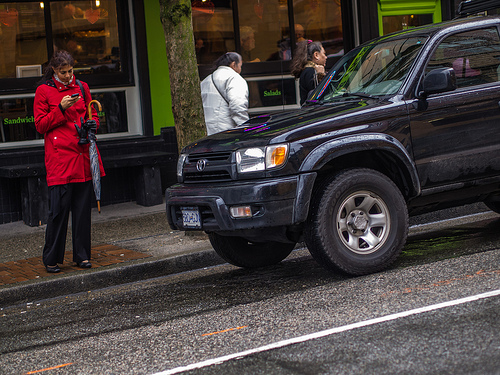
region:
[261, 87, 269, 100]
green letter on sign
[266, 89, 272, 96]
green letter on sign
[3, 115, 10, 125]
green letter on sign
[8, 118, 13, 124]
green letter on sign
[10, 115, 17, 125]
green letter on sign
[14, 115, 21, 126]
green letter on sign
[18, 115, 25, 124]
green letter on sign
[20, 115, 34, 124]
green letter on sign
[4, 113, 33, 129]
green letters on sign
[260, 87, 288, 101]
green letters on sign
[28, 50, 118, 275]
A woman in red jacket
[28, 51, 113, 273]
A woman holding an umbrella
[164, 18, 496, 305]
Black Toyota SUV on the right lane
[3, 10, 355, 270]
People standing on the side walk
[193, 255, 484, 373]
White line on the black asphalt road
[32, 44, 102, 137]
A woman reading messages on the cellphone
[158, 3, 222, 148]
Trunk of the tree planted on the side walk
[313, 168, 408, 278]
Black tire with silver rim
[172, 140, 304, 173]
Headlights of the car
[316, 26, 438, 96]
Front windshield and vipers of the car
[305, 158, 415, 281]
the left front wheel of a car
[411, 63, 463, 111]
the left mirror of a car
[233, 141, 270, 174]
the left headlight of a car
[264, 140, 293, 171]
the left turn signal of a car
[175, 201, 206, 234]
the front license plate of a car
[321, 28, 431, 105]
the front windshield of a car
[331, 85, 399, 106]
a windshield wiper on a window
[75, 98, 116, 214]
a woman holding an umbrella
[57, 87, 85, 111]
a cell phone in someone's hand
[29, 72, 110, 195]
a woman in a red coat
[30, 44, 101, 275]
woman standing on edge of sidewalk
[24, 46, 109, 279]
woman dressed in red coat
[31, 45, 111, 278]
woman carrying a folded umbrella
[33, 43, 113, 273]
woman looking at her cell phone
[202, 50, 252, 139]
woman walking down sidewalk with head slightly lowered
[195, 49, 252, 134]
woman walking down sidewalk with a white coat on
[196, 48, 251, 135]
woman walking down sidewalk with purse draped across chest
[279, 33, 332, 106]
woman with pony tail walking down sidewalk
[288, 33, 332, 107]
woman in black shirt walking down sidewalk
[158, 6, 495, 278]
black suv type vehicle parked at curb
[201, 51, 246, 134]
a woman wearing a white coat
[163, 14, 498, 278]
a black parked car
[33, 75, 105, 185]
woman wearing a red coat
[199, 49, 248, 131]
a woman walking on a sidewalk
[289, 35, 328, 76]
a woman with long brown hair in a pony tail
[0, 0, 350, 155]
store front of a restaurant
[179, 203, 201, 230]
a blue and white license plate on a car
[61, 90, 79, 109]
a woman holding a cell phone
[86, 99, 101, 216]
a woman holding an umbrella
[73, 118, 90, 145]
a black leather glove